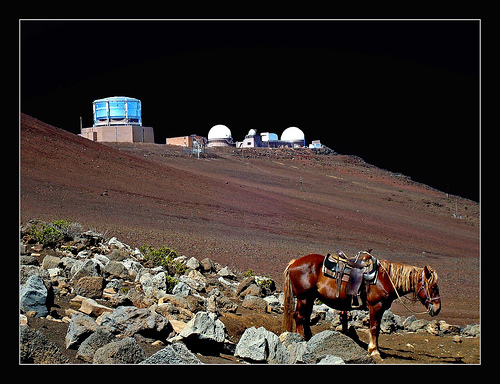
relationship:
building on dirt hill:
[241, 126, 263, 148] [12, 111, 467, 248]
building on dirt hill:
[260, 130, 279, 145] [12, 111, 467, 248]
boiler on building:
[92, 91, 143, 125] [77, 124, 156, 144]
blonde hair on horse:
[365, 246, 440, 293] [272, 232, 460, 361]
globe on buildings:
[205, 123, 232, 140] [203, 121, 238, 148]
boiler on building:
[92, 91, 143, 125] [101, 124, 127, 141]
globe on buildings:
[278, 121, 308, 143] [280, 126, 306, 147]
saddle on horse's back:
[310, 246, 380, 298] [291, 240, 430, 320]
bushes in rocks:
[149, 246, 168, 265] [174, 253, 206, 278]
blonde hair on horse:
[365, 246, 432, 287] [273, 227, 448, 337]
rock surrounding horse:
[295, 327, 372, 364] [273, 241, 450, 362]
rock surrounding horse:
[143, 341, 208, 364] [273, 241, 450, 362]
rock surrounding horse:
[166, 309, 236, 343] [273, 241, 450, 362]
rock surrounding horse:
[72, 272, 105, 293] [273, 241, 450, 362]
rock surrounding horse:
[239, 295, 264, 310] [273, 241, 450, 362]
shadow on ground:
[384, 343, 461, 360] [20, 234, 479, 361]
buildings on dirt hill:
[74, 93, 156, 147] [12, 111, 467, 248]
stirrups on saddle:
[347, 290, 364, 309] [320, 245, 380, 322]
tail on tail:
[280, 258, 294, 331] [280, 258, 294, 331]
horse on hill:
[273, 241, 450, 362] [14, 113, 471, 338]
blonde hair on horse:
[365, 246, 440, 293] [273, 241, 450, 362]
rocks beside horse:
[235, 321, 375, 363] [273, 241, 450, 362]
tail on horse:
[280, 258, 294, 331] [273, 241, 450, 362]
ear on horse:
[423, 264, 431, 279] [273, 241, 450, 362]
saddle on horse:
[310, 246, 388, 300] [273, 241, 450, 362]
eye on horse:
[429, 284, 437, 294] [261, 240, 446, 367]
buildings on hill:
[74, 93, 156, 147] [22, 109, 477, 363]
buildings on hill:
[163, 132, 208, 144] [22, 109, 477, 363]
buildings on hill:
[203, 121, 238, 148] [22, 109, 477, 363]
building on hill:
[241, 126, 263, 148] [22, 109, 477, 363]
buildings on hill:
[280, 126, 306, 147] [22, 109, 477, 363]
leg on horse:
[368, 300, 384, 361] [273, 241, 450, 362]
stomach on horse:
[314, 288, 365, 310] [284, 248, 451, 355]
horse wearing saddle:
[273, 241, 450, 362] [322, 245, 379, 307]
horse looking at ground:
[273, 241, 450, 362] [20, 110, 484, 363]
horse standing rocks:
[273, 241, 450, 362] [71, 247, 221, 328]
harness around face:
[421, 291, 454, 316] [403, 243, 479, 333]